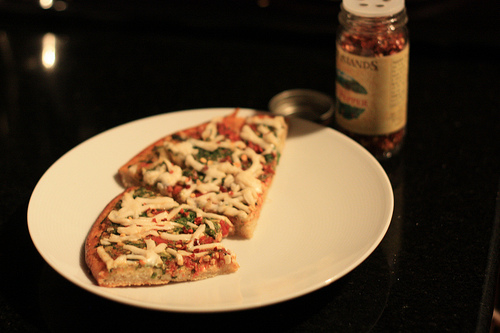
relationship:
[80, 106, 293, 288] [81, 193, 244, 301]
two pizza pieces slices of pizza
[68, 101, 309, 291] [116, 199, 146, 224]
pizza has cheese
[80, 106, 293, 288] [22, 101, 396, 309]
two pizza pieces on one plate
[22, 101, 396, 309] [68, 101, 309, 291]
one plate has two slices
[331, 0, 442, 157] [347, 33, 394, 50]
container of condiment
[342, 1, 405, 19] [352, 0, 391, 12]
covering with round holes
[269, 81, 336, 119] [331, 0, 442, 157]
lid covers condiment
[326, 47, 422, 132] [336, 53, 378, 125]
label has writing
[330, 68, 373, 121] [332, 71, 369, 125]
semicircles on front of bottle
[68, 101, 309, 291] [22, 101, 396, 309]
pizza on plate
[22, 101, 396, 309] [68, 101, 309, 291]
plate has pizza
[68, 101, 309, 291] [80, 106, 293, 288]
pizza has two pizza pieces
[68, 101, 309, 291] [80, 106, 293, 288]
pizza are in two pizza pieces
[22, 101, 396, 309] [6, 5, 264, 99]
plate located on table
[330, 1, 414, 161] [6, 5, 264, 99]
bottle on table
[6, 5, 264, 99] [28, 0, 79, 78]
table has reflection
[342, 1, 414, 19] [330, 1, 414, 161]
cover of bottle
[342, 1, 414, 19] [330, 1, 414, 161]
cover for container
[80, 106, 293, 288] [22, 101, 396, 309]
two pizza pieces on plate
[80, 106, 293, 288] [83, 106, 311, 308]
two pizza pieces in middle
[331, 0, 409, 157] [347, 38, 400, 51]
container contains peppers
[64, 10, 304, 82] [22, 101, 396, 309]
black surface under plate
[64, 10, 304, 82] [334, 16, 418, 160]
black surface under spice container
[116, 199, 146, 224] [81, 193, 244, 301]
cheese on top of pizza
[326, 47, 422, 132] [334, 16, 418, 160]
label on spice container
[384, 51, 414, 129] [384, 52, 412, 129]
label on side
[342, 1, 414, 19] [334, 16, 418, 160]
cover on spice container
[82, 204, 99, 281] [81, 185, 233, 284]
crust on pizza piece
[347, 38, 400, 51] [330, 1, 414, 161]
peppers in jar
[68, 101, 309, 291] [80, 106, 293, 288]
pizza in two pizza pieces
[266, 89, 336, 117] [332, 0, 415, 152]
cover covers spice jar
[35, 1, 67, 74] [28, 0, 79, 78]
light has reflection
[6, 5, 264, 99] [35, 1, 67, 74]
table reflects light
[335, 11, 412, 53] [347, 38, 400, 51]
jar contains peppers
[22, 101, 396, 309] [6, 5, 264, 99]
plate on table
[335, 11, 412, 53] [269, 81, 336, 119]
jar contains lid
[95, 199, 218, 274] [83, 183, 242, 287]
cheese on top of pizza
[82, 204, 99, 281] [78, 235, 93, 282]
crust on bottom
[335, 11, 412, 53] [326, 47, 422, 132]
jar contains label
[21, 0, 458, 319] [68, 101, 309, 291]
meal contains pizza